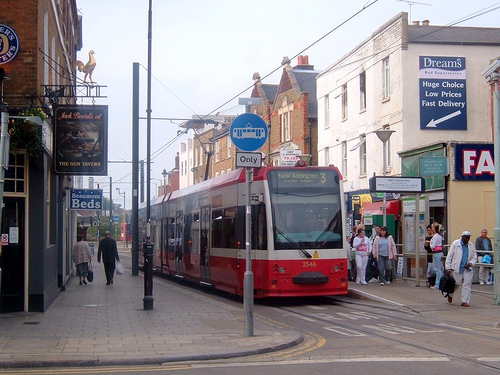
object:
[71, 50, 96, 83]
statue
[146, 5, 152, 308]
post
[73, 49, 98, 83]
rooster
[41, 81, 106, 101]
pole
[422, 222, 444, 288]
two woman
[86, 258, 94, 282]
bag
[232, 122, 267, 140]
white bus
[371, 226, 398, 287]
person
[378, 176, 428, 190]
white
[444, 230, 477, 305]
man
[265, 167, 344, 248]
window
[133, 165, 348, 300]
bus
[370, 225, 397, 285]
woman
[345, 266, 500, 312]
sidewalk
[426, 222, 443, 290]
person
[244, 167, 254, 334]
post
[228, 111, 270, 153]
blue sign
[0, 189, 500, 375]
street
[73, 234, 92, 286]
people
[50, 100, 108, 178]
sign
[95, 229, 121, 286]
man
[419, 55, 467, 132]
advertisement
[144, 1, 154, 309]
lamp post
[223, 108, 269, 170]
sign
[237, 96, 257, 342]
post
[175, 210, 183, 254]
window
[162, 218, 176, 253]
window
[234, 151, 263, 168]
sign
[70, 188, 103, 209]
sign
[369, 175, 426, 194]
sign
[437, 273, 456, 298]
suitcase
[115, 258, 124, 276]
bag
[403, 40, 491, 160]
wall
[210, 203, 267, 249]
window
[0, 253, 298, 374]
sidewalk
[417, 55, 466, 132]
sign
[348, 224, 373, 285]
lady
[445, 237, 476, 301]
white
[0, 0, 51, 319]
wall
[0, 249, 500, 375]
pavement